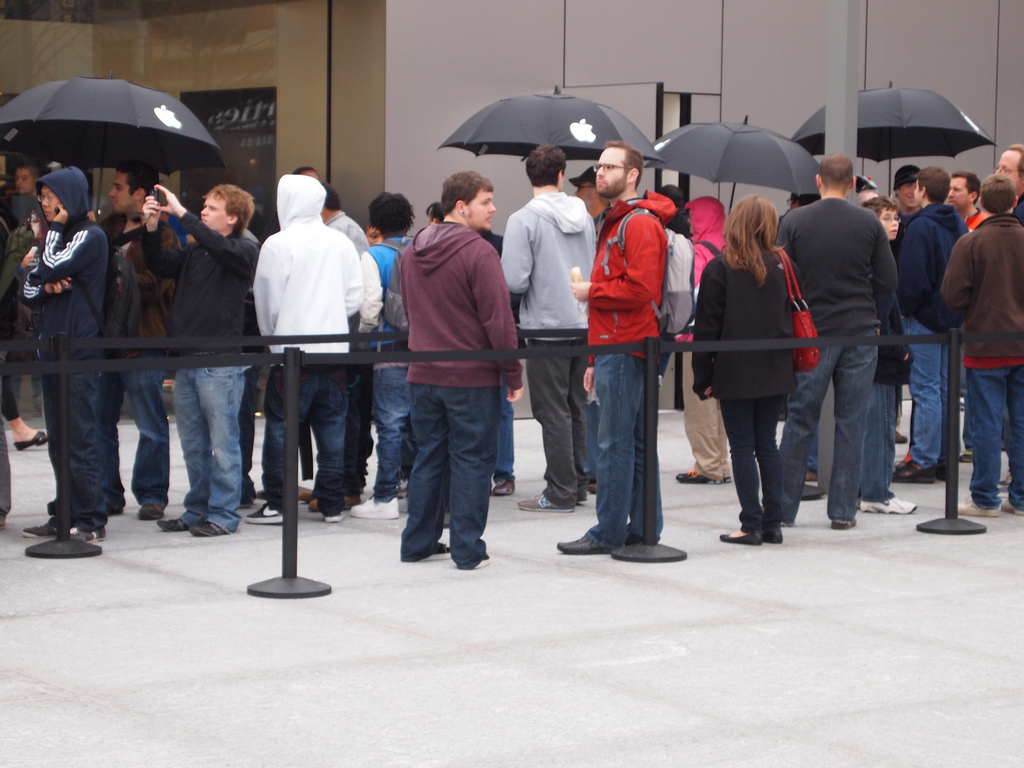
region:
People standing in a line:
[8, 75, 1002, 541]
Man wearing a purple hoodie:
[392, 152, 549, 576]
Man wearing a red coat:
[561, 132, 667, 562]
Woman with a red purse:
[711, 190, 829, 582]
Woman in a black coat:
[686, 193, 833, 567]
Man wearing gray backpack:
[547, 136, 702, 570]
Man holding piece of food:
[543, 139, 696, 561]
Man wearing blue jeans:
[555, 139, 692, 573]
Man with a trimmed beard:
[559, 130, 711, 577]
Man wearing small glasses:
[547, 143, 699, 596]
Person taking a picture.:
[143, 179, 262, 538]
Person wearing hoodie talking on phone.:
[23, 163, 110, 540]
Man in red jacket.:
[551, 142, 672, 553]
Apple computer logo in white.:
[560, 109, 602, 142]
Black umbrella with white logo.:
[3, 75, 223, 178]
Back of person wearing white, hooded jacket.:
[254, 166, 363, 518]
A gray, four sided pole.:
[819, 0, 870, 166]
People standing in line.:
[7, 151, 1020, 553]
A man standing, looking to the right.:
[392, 172, 526, 574]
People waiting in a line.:
[8, 55, 1007, 524]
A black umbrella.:
[11, 55, 239, 208]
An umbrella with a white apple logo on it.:
[438, 90, 653, 170]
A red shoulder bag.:
[767, 241, 828, 375]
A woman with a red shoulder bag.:
[672, 187, 828, 542]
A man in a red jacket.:
[572, 136, 674, 564]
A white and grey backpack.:
[662, 226, 704, 353]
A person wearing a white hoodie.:
[252, 155, 357, 358]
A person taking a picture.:
[138, 171, 279, 564]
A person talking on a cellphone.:
[24, 168, 126, 580]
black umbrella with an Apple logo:
[11, 70, 212, 168]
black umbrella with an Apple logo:
[655, 107, 827, 199]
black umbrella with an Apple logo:
[798, 77, 994, 158]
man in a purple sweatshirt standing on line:
[403, 175, 522, 569]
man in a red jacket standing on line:
[581, 142, 673, 553]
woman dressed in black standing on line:
[698, 193, 817, 545]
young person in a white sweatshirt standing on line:
[265, 169, 367, 520]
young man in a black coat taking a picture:
[135, 175, 259, 542]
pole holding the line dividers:
[246, 348, 326, 606]